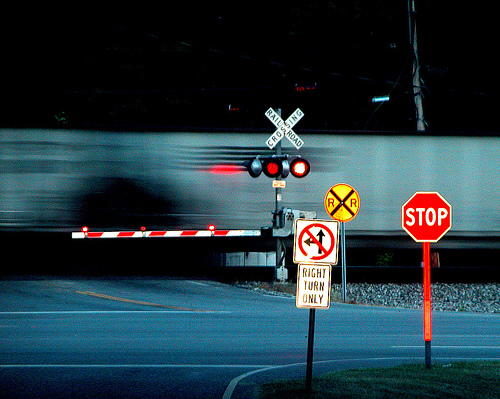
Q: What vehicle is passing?
A: A train.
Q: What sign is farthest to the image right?
A: Stop sign.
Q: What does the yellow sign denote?
A: Railriad crossing.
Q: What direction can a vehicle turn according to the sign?
A: Right.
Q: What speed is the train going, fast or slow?
A: Fast.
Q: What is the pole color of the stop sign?
A: Red.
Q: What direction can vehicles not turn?
A: Left.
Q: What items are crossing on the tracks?
A: Boxcars.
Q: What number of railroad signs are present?
A: Two.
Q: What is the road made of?
A: Asphalt.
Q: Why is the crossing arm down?
A: Because the train is going by.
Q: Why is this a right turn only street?
A: Because the street is one way.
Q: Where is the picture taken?
A: At an street intersection and railroad crossing?.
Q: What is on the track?
A: A moving train.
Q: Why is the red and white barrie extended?
A: To stop traffic, while the train passes by.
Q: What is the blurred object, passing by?
A: A train..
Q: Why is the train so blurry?
A: It is speeding by.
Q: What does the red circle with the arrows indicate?
A: Right turn only.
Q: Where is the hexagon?
A: On a stop sign.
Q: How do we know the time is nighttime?
A: The sky is black.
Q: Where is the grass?
A: On the curb, with the stop sign.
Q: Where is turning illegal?
A: To the left.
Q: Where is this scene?
A: Railroad.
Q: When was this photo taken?
A: At night.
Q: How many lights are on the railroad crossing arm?
A: Three.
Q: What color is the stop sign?
A: Red.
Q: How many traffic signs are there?
A: Four.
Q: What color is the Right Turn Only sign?
A: White.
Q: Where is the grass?
A: By the stop sign.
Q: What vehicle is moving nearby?
A: Train.